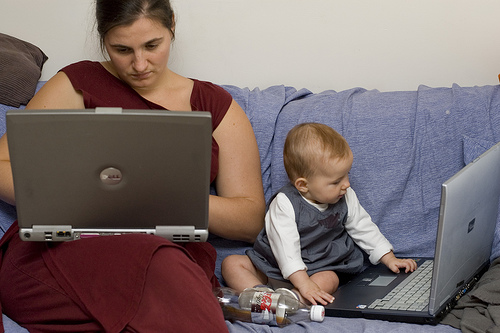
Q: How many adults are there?
A: One.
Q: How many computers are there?
A: Two.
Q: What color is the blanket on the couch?
A: Blue.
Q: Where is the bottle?
A: On the couch.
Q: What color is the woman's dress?
A: Red.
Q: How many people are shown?
A: 2.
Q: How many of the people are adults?
A: One.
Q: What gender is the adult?
A: Female.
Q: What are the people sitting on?
A: Couch.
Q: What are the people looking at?
A: Laptops.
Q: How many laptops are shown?
A: 2.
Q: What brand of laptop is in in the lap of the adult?
A: DELL.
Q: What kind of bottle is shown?
A: Soda.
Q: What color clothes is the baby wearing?
A: Gray and white.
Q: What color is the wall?
A: Light gray.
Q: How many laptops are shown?
A: Two.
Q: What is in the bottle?
A: Soda.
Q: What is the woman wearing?
A: Dress.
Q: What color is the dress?
A: Red.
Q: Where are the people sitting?
A: Sofa.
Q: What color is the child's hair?
A: Reddish.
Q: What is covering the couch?
A: Blanket.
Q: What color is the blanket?
A: Blue.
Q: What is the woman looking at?
A: Laptop.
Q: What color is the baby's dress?
A: Gray.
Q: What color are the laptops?
A: Gray.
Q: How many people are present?
A: Two.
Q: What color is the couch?
A: Blue.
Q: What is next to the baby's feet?
A: Bottle.